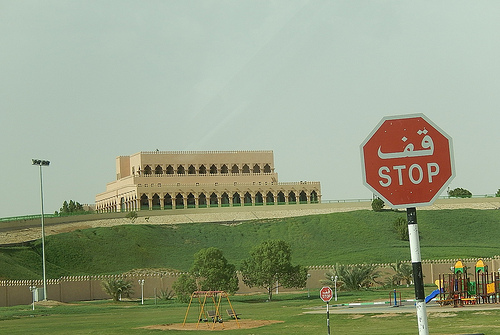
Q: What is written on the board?
A: STOP.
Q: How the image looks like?
A: Cool.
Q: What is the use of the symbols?
A: To avoid accidents.